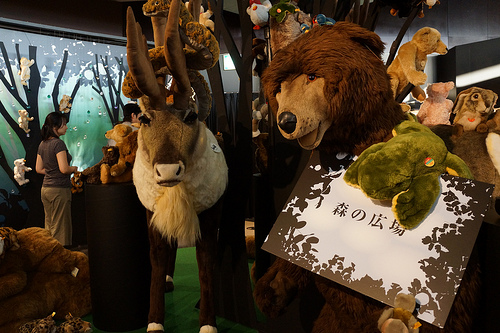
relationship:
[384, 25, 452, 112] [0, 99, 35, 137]
bear on tree limb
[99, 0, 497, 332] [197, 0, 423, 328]
stuffed toys around toy tree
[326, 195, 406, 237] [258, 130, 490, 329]
info on card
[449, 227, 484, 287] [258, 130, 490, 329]
border on card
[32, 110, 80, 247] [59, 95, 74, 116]
woman standing beside stuffed animal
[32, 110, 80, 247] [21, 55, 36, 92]
woman standing beside stuffed animal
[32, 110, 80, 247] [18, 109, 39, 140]
woman standing beside stuffed animal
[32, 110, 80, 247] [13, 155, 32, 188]
woman standing beside stuffed animal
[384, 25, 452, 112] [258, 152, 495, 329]
bear holding sign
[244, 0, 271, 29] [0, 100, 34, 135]
bird on branch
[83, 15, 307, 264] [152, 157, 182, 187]
deer has nose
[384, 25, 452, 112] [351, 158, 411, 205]
bear has nose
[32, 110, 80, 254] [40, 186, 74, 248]
woman wearing pants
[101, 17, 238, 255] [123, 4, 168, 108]
goat has deer antlers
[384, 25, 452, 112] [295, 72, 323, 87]
bear has eye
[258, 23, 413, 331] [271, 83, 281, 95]
bear has eye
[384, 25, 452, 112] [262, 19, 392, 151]
bear has head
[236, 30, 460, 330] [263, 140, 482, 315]
bear has card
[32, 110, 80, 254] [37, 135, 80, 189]
woman has shirt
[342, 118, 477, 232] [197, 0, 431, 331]
stuffed toys on toy tree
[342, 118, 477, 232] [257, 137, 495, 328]
stuffed toys on board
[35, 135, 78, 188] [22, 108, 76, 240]
shirt on woman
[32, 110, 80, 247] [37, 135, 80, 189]
woman wearing shirt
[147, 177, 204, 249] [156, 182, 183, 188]
hair on chin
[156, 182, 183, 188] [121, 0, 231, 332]
chin on deer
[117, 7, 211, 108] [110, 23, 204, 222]
deer antlers on deer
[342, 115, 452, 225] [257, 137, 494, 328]
stuffed anmal on board